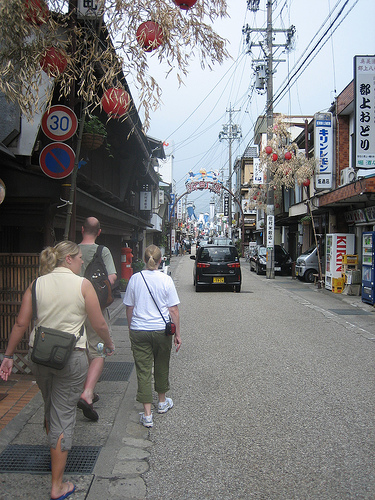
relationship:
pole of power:
[240, 4, 287, 279] [232, 1, 297, 96]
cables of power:
[167, 2, 328, 159] [232, 1, 297, 96]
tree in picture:
[5, 0, 221, 145] [5, 2, 370, 499]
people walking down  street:
[0, 209, 186, 500] [83, 286, 142, 494]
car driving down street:
[187, 236, 248, 297] [171, 239, 305, 477]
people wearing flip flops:
[0, 238, 117, 500] [39, 446, 80, 497]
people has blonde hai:
[0, 238, 117, 500] [30, 235, 93, 279]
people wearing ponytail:
[0, 238, 117, 500] [30, 235, 93, 279]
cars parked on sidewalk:
[243, 239, 324, 283] [249, 272, 374, 366]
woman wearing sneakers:
[121, 240, 188, 433] [137, 395, 182, 432]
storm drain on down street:
[5, 436, 103, 472] [141, 254, 374, 500]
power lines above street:
[217, 2, 324, 98] [171, 239, 305, 477]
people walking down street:
[0, 209, 186, 500] [171, 239, 305, 477]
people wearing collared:
[0, 238, 117, 500] [48, 264, 81, 275]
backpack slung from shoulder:
[82, 243, 118, 310] [90, 239, 109, 269]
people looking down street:
[0, 238, 117, 500] [141, 254, 374, 500]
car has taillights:
[187, 236, 248, 297] [198, 258, 242, 272]